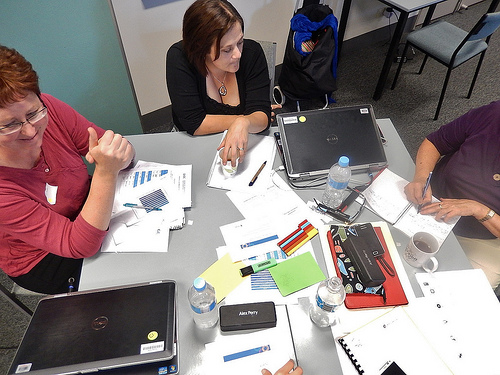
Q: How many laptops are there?
A: Two.